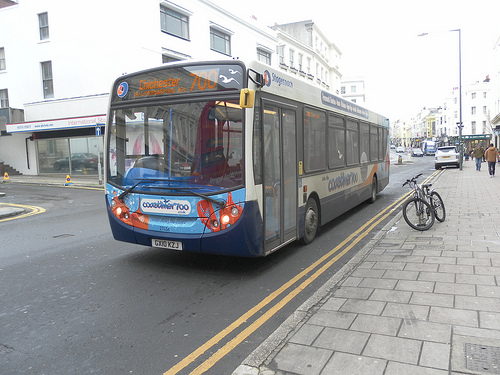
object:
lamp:
[416, 23, 471, 137]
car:
[431, 142, 464, 171]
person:
[483, 140, 498, 176]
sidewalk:
[388, 157, 500, 368]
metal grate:
[410, 172, 435, 225]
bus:
[100, 55, 392, 258]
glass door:
[257, 91, 310, 252]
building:
[0, 2, 374, 131]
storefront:
[434, 131, 490, 161]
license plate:
[150, 238, 182, 252]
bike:
[397, 169, 448, 233]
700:
[184, 68, 218, 93]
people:
[470, 142, 485, 173]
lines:
[152, 240, 352, 374]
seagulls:
[217, 74, 239, 86]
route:
[103, 69, 251, 104]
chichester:
[138, 75, 183, 90]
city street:
[8, 210, 371, 359]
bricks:
[359, 332, 423, 367]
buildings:
[454, 69, 495, 154]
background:
[351, 87, 488, 153]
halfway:
[384, 125, 500, 232]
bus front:
[102, 59, 267, 267]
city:
[6, 1, 500, 375]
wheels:
[455, 160, 464, 168]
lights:
[209, 96, 290, 122]